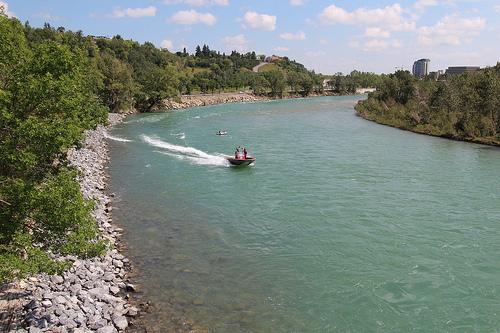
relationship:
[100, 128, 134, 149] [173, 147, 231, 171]
waves form from boat wake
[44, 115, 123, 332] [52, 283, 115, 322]
riverbank covered by rocks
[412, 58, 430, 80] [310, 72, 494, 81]
buildings close to horizon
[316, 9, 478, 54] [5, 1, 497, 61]
clouds cover sky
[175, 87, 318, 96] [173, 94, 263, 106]
roadway on top of a ridge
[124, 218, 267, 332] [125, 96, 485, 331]
rocks are at bottom of river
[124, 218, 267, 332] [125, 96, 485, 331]
rocks are beneath river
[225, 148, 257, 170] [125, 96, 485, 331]
speedboat traveling on river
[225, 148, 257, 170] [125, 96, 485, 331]
speedboat on top of river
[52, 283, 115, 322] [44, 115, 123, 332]
rocks are on riverbank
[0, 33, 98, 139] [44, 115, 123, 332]
trees are along riverbank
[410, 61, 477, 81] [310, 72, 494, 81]
buildings are at horizon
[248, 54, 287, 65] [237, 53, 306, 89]
buildings are at top of a hill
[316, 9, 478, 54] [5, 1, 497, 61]
clouds are scattered in sky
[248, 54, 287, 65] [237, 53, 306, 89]
buildings are on top of a hill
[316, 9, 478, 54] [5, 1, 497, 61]
clouds covering sky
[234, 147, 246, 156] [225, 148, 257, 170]
people are on speedboat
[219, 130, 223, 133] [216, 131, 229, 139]
people are on mini-boat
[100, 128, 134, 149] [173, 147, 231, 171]
waves coming from boat wake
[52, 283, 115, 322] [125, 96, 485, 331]
rocks are left of river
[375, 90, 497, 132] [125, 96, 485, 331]
trees right of river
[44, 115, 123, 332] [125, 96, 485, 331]
riverbank to left of a river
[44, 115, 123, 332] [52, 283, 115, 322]
riverbank covered with rocks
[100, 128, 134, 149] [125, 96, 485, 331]
waves form on top of river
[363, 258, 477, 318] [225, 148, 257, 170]
whirlpool forms ahead of speedboat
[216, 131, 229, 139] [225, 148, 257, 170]
mini-boat behind speedboat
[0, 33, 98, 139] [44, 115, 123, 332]
trees alongside riverbank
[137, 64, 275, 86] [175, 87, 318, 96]
trees along roadway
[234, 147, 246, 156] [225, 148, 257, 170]
people standing up in speedboat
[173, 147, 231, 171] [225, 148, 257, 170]
boat wake forms behind speedboat